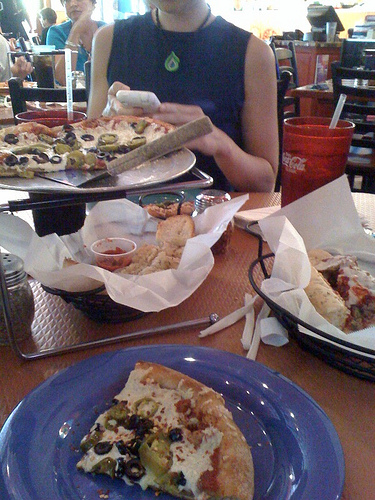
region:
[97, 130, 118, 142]
Jalapenos are on the pizza.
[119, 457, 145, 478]
Olives are on the pizza.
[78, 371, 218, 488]
Cheese is on the pizza.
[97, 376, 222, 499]
Sauce is on the pizza.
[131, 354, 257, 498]
The crust is white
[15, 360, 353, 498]
The plate is blue.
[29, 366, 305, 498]
The pizza is on the plate.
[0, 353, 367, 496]
The plate is on the table.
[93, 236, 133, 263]
Sauce is in the cup.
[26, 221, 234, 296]
Bread is in the basket.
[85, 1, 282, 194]
Girl sitting at table in front of pizza.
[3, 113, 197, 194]
Pizza sitting in front of girl.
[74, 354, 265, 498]
Slice of pizza sitting on plate.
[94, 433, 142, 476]
Black olives on pizza.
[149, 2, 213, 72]
Necklace around girl's neck.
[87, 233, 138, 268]
Small cup of marinara sauce.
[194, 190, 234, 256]
Shaker of red pepper flakes.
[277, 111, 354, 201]
Big red drink cup sitting on table.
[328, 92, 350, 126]
Tip of plastic straw inside drink cup.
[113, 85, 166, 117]
Girl holding white cell phone in hands.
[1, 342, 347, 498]
Pizza on a plate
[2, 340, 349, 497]
Pizza on a blue plate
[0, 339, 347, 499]
Pizza on a round plate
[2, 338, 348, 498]
Pizza on a round blue plate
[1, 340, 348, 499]
Slice of pizza on a plate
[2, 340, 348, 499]
Slice of pizza on a blue plate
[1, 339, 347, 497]
Slice of pizza on a round plate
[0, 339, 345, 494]
Slice of pizza on a round blue plate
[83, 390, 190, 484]
Olives on a pizza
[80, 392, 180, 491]
Jalapenos on a pizza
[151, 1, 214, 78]
Green tear pendant necklace.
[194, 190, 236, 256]
Crushed red pepper shaker.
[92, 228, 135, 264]
Small plastic cup with red sauce.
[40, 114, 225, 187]
Metal and wood pie server.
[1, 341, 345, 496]
Blue dish with a slice of pizza on it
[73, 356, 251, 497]
One slice of pizza with black olives and jalapenos.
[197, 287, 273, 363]
Empty white straw wrappers.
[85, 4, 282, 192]
Person in black top sitting at table.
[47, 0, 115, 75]
Woman wearing blue shirt.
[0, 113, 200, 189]
Half of a pizza on silver serving tray.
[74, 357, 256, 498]
A big slice of pizza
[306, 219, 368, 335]
A meatball and cheese sub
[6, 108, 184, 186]
Half of a large pizza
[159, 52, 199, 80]
A green and blue pendant on a woman's necklace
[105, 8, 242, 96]
A woman's pendant necklance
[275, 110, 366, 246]
A red cup with a Coco Cola logo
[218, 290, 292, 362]
A folded straw wrapper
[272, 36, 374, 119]
A table with empty chairs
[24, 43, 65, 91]
Soft drink in a white cup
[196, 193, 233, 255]
A shaker of pepper on a table